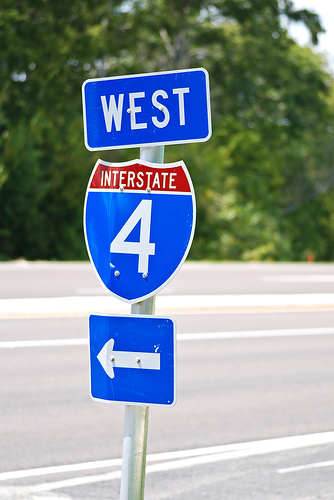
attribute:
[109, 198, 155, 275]
number 4 — white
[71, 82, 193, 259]
sign — blue, red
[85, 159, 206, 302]
four — large, printed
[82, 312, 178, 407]
sign — blue, small, directional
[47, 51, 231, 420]
sign — blue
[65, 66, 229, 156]
sign — west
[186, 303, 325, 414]
road — empty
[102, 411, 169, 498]
pole — silver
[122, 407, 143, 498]
pole — silver, metal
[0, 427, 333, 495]
lines — white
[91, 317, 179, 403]
left turn — blue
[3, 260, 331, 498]
street — grey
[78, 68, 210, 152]
signs — traffic signs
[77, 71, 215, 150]
sign — small, blue, directional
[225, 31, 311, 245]
trees — green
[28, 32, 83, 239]
trees — green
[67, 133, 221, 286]
sign — indicating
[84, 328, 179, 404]
arrow — white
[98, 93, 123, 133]
letter — white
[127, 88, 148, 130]
letter — white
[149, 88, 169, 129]
letter — white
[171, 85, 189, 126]
letter — white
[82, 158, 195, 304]
sign — small, red, blue, blue and red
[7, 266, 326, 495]
road — gray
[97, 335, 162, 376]
arrow — white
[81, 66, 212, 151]
street sign — white, blue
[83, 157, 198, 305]
street sign — white, blue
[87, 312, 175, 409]
street sign — white, blue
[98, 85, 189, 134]
word — west